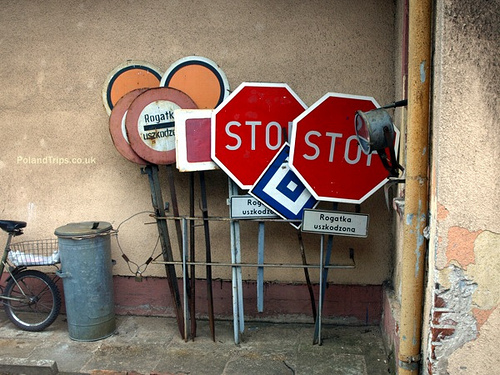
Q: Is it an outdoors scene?
A: Yes, it is outdoors.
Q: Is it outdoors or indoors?
A: It is outdoors.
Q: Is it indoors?
A: No, it is outdoors.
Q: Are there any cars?
A: No, there are no cars.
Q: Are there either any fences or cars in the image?
A: No, there are no cars or fences.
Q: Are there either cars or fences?
A: No, there are no cars or fences.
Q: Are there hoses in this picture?
A: No, there are no hoses.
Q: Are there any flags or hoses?
A: No, there are no hoses or flags.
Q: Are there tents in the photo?
A: No, there are no tents.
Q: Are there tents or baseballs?
A: No, there are no tents or baseballs.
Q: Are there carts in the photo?
A: No, there are no carts.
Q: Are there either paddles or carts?
A: No, there are no carts or paddles.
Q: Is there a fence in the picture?
A: No, there are no fences.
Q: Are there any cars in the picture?
A: No, there are no cars.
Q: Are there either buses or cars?
A: No, there are no cars or buses.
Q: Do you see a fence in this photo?
A: No, there are no fences.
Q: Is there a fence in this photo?
A: No, there are no fences.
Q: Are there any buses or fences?
A: No, there are no buses or fences.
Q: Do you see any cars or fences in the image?
A: No, there are no fences or cars.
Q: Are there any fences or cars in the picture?
A: No, there are no fences or cars.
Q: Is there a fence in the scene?
A: No, there are no fences.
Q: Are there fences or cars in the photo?
A: No, there are no fences or cars.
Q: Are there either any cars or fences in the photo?
A: No, there are no fences or cars.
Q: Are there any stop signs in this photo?
A: Yes, there is a stop sign.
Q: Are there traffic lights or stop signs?
A: Yes, there is a stop sign.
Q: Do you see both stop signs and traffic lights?
A: No, there is a stop sign but no traffic lights.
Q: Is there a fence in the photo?
A: No, there are no fences.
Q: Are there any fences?
A: No, there are no fences.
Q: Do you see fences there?
A: No, there are no fences.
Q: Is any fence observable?
A: No, there are no fences.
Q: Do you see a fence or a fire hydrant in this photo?
A: No, there are no fences or fire hydrants.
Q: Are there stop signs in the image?
A: Yes, there is a stop sign.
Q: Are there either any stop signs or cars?
A: Yes, there is a stop sign.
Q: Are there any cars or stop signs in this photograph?
A: Yes, there is a stop sign.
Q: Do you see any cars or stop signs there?
A: Yes, there is a stop sign.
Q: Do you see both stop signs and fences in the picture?
A: No, there is a stop sign but no fences.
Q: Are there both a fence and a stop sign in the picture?
A: No, there is a stop sign but no fences.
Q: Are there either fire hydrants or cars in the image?
A: No, there are no cars or fire hydrants.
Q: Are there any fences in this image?
A: No, there are no fences.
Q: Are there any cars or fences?
A: No, there are no fences or cars.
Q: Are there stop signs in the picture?
A: Yes, there is a stop sign.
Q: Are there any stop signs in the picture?
A: Yes, there is a stop sign.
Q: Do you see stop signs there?
A: Yes, there is a stop sign.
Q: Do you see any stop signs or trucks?
A: Yes, there is a stop sign.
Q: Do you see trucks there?
A: No, there are no trucks.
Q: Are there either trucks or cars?
A: No, there are no trucks or cars.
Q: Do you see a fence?
A: No, there are no fences.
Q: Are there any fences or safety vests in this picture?
A: No, there are no fences or safety vests.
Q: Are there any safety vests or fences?
A: No, there are no fences or safety vests.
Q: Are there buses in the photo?
A: No, there are no buses.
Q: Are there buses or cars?
A: No, there are no buses or cars.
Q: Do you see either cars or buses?
A: No, there are no buses or cars.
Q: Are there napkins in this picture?
A: No, there are no napkins.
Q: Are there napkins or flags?
A: No, there are no napkins or flags.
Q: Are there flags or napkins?
A: No, there are no napkins or flags.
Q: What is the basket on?
A: The basket is on the bicycle.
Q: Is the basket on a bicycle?
A: Yes, the basket is on a bicycle.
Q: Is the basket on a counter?
A: No, the basket is on a bicycle.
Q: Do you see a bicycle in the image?
A: Yes, there is a bicycle.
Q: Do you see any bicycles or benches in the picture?
A: Yes, there is a bicycle.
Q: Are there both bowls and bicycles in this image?
A: No, there is a bicycle but no bowls.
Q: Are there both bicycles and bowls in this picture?
A: No, there is a bicycle but no bowls.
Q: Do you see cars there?
A: No, there are no cars.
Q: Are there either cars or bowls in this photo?
A: No, there are no cars or bowls.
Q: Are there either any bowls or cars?
A: No, there are no cars or bowls.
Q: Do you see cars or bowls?
A: No, there are no cars or bowls.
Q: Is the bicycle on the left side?
A: Yes, the bicycle is on the left of the image.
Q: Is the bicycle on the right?
A: No, the bicycle is on the left of the image.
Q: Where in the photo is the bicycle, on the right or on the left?
A: The bicycle is on the left of the image.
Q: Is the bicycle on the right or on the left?
A: The bicycle is on the left of the image.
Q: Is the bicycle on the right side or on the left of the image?
A: The bicycle is on the left of the image.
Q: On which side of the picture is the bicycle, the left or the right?
A: The bicycle is on the left of the image.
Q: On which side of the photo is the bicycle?
A: The bicycle is on the left of the image.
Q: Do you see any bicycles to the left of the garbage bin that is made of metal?
A: Yes, there is a bicycle to the left of the garbage can.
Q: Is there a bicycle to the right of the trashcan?
A: No, the bicycle is to the left of the trashcan.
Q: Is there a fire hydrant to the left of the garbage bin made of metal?
A: No, there is a bicycle to the left of the trash bin.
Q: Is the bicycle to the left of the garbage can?
A: Yes, the bicycle is to the left of the garbage can.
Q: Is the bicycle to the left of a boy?
A: No, the bicycle is to the left of the garbage can.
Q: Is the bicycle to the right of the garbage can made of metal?
A: No, the bicycle is to the left of the garbage can.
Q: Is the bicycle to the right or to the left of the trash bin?
A: The bicycle is to the left of the trash bin.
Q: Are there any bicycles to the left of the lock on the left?
A: Yes, there is a bicycle to the left of the lock.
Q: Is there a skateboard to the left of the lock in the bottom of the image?
A: No, there is a bicycle to the left of the lock.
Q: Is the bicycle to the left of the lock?
A: Yes, the bicycle is to the left of the lock.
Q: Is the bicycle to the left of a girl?
A: No, the bicycle is to the left of the lock.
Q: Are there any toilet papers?
A: No, there are no toilet papers.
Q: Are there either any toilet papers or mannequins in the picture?
A: No, there are no toilet papers or mannequins.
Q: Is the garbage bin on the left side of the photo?
A: Yes, the garbage bin is on the left of the image.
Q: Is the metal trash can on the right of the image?
A: No, the garbage bin is on the left of the image.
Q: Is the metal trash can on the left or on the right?
A: The trashcan is on the left of the image.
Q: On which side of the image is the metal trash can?
A: The garbage can is on the left of the image.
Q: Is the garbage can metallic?
A: Yes, the garbage can is metallic.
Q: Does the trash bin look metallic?
A: Yes, the trash bin is metallic.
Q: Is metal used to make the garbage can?
A: Yes, the garbage can is made of metal.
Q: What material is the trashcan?
A: The trashcan is made of metal.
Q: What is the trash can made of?
A: The trashcan is made of metal.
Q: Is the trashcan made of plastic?
A: No, the trashcan is made of metal.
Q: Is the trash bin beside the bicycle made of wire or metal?
A: The garbage can is made of metal.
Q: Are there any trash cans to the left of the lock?
A: Yes, there is a trash can to the left of the lock.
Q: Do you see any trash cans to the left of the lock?
A: Yes, there is a trash can to the left of the lock.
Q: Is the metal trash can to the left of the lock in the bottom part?
A: Yes, the trash bin is to the left of the lock.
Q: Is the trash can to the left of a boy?
A: No, the trash can is to the left of the lock.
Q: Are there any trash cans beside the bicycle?
A: Yes, there is a trash can beside the bicycle.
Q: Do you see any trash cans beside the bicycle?
A: Yes, there is a trash can beside the bicycle.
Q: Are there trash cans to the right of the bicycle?
A: Yes, there is a trash can to the right of the bicycle.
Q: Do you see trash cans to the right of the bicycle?
A: Yes, there is a trash can to the right of the bicycle.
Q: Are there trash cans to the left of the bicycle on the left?
A: No, the trash can is to the right of the bicycle.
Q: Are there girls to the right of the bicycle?
A: No, there is a trash can to the right of the bicycle.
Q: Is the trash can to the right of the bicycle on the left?
A: Yes, the trash can is to the right of the bicycle.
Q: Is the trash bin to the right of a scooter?
A: No, the trash bin is to the right of the bicycle.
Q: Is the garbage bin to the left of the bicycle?
A: No, the garbage bin is to the right of the bicycle.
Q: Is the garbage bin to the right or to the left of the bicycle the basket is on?
A: The garbage bin is to the right of the bicycle.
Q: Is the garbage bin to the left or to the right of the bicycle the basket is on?
A: The garbage bin is to the right of the bicycle.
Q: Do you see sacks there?
A: No, there are no sacks.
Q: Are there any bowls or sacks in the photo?
A: No, there are no sacks or bowls.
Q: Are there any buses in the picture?
A: No, there are no buses.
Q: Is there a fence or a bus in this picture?
A: No, there are no buses or fences.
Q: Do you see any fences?
A: No, there are no fences.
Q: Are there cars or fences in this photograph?
A: No, there are no fences or cars.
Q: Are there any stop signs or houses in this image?
A: Yes, there is a stop sign.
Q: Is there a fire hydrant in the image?
A: No, there are no fire hydrants.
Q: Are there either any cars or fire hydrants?
A: No, there are no fire hydrants or cars.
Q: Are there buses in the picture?
A: No, there are no buses.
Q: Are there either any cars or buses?
A: No, there are no buses or cars.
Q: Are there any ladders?
A: No, there are no ladders.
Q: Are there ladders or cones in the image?
A: No, there are no ladders or cones.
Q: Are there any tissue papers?
A: No, there are no tissue papers.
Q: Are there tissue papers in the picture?
A: No, there are no tissue papers.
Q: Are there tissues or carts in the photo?
A: No, there are no tissues or carts.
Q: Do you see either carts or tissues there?
A: No, there are no tissues or carts.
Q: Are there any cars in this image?
A: No, there are no cars.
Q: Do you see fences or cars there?
A: No, there are no cars or fences.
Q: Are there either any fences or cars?
A: No, there are no cars or fences.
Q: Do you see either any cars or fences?
A: No, there are no cars or fences.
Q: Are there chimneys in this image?
A: No, there are no chimneys.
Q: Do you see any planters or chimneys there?
A: No, there are no chimneys or planters.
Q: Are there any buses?
A: No, there are no buses.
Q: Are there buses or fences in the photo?
A: No, there are no buses or fences.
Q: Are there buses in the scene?
A: No, there are no buses.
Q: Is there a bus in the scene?
A: No, there are no buses.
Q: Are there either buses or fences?
A: No, there are no buses or fences.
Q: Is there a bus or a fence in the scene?
A: No, there are no buses or fences.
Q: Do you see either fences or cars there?
A: No, there are no fences or cars.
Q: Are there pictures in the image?
A: No, there are no pictures.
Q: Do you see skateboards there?
A: No, there are no skateboards.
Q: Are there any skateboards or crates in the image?
A: No, there are no skateboards or crates.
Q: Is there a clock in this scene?
A: No, there are no clocks.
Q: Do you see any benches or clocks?
A: No, there are no clocks or benches.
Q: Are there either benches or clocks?
A: No, there are no clocks or benches.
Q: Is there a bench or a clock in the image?
A: No, there are no clocks or benches.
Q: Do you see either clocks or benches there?
A: No, there are no clocks or benches.